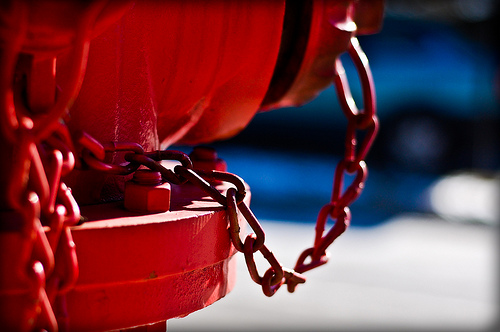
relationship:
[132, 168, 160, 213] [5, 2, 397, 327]
screw on fire hydrant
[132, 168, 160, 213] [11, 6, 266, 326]
screw on hydrant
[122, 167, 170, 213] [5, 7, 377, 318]
screw on base of hydrant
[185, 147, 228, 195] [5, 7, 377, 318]
screw on base of hydrant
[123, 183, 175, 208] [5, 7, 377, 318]
fastener on hydrant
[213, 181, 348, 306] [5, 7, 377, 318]
chain connected to hydrant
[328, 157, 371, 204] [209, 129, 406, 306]
link of chain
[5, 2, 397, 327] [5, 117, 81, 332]
fire hydrant with chain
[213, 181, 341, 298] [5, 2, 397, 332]
chain hanging from fire hydrant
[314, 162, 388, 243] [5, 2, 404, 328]
link of chain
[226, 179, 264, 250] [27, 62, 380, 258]
link of chain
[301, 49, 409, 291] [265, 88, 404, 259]
link of chain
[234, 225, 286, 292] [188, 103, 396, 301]
link of chain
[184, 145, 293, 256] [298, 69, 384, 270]
link of chain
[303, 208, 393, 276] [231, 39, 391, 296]
link of chain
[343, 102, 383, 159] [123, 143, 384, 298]
link of chain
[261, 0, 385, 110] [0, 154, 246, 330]
water spout has base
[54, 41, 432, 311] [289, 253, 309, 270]
chain has edge